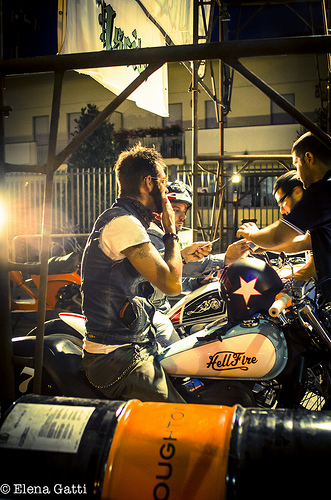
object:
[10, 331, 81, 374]
seat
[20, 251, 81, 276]
seat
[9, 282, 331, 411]
bike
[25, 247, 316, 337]
bike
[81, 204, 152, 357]
vest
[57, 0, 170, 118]
banner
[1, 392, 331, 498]
barrel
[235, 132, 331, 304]
men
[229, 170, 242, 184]
light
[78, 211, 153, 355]
shirt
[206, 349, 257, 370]
hellfire logo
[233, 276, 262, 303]
star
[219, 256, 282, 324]
helmet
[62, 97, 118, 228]
tree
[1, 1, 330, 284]
building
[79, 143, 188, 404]
motorcyclist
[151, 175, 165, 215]
beard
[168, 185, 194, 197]
goggles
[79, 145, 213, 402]
boy